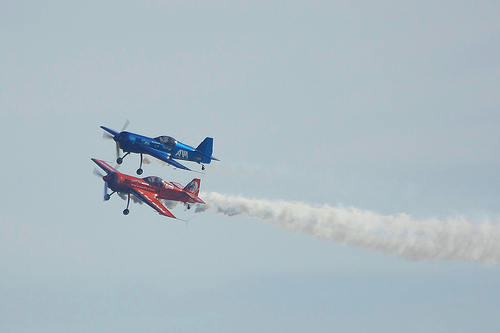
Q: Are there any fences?
A: No, there are no fences.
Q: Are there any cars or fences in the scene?
A: No, there are no fences or cars.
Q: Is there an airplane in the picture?
A: Yes, there is an airplane.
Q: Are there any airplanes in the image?
A: Yes, there is an airplane.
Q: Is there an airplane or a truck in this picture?
A: Yes, there is an airplane.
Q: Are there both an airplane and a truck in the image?
A: No, there is an airplane but no trucks.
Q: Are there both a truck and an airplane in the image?
A: No, there is an airplane but no trucks.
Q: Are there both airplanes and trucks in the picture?
A: No, there is an airplane but no trucks.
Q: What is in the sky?
A: The airplane is in the sky.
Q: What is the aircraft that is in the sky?
A: The aircraft is an airplane.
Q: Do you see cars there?
A: No, there are no cars.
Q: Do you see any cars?
A: No, there are no cars.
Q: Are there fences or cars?
A: No, there are no cars or fences.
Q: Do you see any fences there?
A: No, there are no fences.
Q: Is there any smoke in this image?
A: Yes, there is smoke.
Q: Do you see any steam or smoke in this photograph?
A: Yes, there is smoke.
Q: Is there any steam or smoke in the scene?
A: Yes, there is smoke.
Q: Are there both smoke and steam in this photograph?
A: No, there is smoke but no steam.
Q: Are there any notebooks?
A: No, there are no notebooks.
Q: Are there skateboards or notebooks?
A: No, there are no notebooks or skateboards.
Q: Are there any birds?
A: No, there are no birds.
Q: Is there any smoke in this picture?
A: Yes, there is smoke.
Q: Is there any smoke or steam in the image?
A: Yes, there is smoke.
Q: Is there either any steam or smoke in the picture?
A: Yes, there is smoke.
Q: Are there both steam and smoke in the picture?
A: No, there is smoke but no steam.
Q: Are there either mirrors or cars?
A: No, there are no cars or mirrors.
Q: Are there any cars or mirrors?
A: No, there are no cars or mirrors.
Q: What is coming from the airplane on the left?
A: The smoke is coming from the airplane.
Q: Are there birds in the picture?
A: No, there are no birds.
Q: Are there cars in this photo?
A: No, there are no cars.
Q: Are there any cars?
A: No, there are no cars.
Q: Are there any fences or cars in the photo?
A: No, there are no cars or fences.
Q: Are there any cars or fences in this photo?
A: No, there are no cars or fences.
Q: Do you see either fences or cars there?
A: No, there are no cars or fences.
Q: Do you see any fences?
A: No, there are no fences.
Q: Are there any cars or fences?
A: No, there are no fences or cars.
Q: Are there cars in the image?
A: No, there are no cars.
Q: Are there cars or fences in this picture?
A: No, there are no cars or fences.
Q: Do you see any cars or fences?
A: No, there are no cars or fences.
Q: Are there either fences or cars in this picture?
A: No, there are no cars or fences.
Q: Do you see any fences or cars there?
A: No, there are no cars or fences.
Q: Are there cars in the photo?
A: No, there are no cars.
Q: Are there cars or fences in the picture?
A: No, there are no cars or fences.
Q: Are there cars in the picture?
A: No, there are no cars.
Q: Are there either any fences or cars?
A: No, there are no cars or fences.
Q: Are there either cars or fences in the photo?
A: No, there are no cars or fences.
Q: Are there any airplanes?
A: Yes, there is an airplane.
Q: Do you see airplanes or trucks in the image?
A: Yes, there is an airplane.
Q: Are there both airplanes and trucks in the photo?
A: No, there is an airplane but no trucks.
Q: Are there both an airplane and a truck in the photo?
A: No, there is an airplane but no trucks.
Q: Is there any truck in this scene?
A: No, there are no trucks.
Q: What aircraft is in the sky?
A: The aircraft is an airplane.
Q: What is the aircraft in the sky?
A: The aircraft is an airplane.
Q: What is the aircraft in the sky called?
A: The aircraft is an airplane.